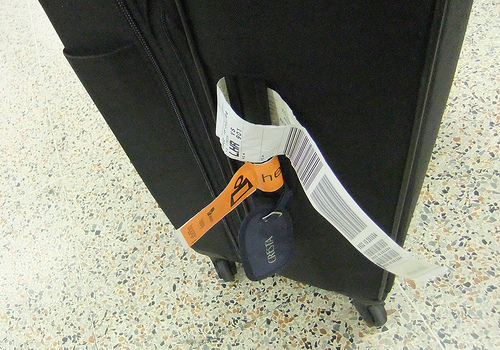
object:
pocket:
[63, 42, 137, 58]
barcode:
[284, 127, 322, 190]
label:
[214, 77, 449, 287]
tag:
[240, 203, 295, 282]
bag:
[38, 1, 473, 327]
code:
[228, 139, 239, 158]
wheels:
[355, 299, 388, 328]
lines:
[0, 176, 63, 211]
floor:
[0, 0, 498, 349]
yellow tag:
[175, 157, 284, 249]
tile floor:
[0, 1, 500, 349]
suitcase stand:
[38, 0, 473, 328]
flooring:
[393, 199, 499, 349]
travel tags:
[214, 75, 447, 287]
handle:
[222, 57, 290, 200]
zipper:
[175, 2, 248, 215]